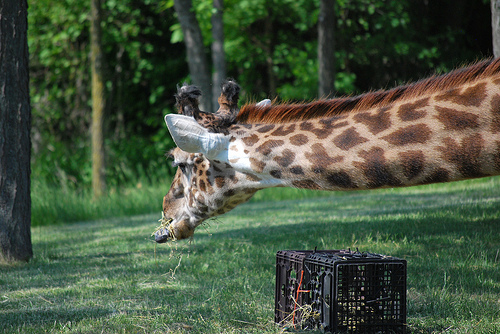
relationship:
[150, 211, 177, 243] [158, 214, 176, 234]
hay in mouth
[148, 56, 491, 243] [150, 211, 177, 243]
giraffe eating hay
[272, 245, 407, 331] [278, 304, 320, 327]
black crate with straw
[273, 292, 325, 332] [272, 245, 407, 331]
straw with black crate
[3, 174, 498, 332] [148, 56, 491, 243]
field with giraffe